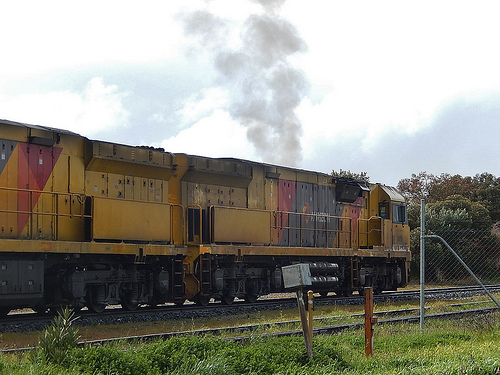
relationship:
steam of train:
[176, 7, 317, 162] [3, 141, 418, 320]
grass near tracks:
[1, 309, 497, 374] [2, 273, 499, 341]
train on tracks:
[0, 112, 425, 282] [0, 280, 484, 330]